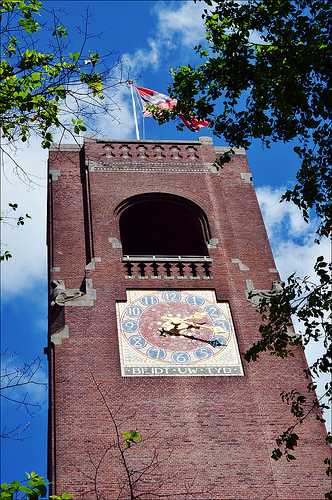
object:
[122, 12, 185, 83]
sky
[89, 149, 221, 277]
building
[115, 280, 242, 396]
clock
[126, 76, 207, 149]
flag